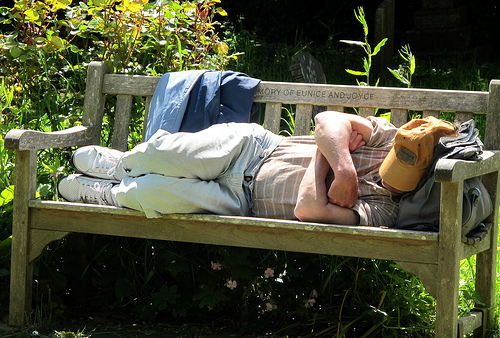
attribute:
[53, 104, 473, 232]
man — sleeping, laying, folding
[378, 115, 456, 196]
hat — yellow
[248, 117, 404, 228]
shirt — brown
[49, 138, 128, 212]
shoes — white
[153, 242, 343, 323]
flowers — red, green, pink, growing, light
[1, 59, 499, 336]
bench — brown, wooden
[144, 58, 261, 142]
jacket — draped, blue, denim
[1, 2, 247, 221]
bush — green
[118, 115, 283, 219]
jeans — white, light, blue